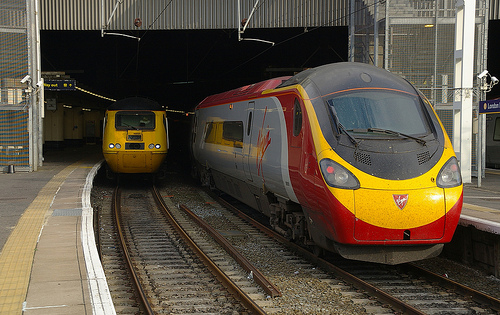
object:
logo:
[392, 194, 409, 211]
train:
[195, 62, 465, 264]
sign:
[46, 99, 57, 111]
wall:
[28, 99, 87, 141]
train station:
[2, 0, 498, 178]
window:
[335, 94, 431, 134]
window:
[203, 121, 245, 146]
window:
[292, 98, 302, 136]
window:
[247, 111, 252, 135]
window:
[117, 115, 152, 128]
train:
[101, 96, 170, 179]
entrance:
[32, 22, 363, 176]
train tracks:
[109, 187, 261, 314]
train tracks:
[202, 267, 490, 314]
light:
[155, 144, 161, 149]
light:
[109, 143, 115, 148]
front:
[103, 102, 167, 166]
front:
[305, 58, 465, 259]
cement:
[1, 149, 117, 314]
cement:
[430, 157, 499, 220]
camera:
[17, 74, 45, 96]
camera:
[475, 65, 497, 96]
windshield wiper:
[326, 100, 360, 146]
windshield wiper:
[339, 127, 426, 144]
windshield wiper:
[119, 120, 137, 130]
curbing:
[0, 154, 76, 312]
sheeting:
[1, 0, 498, 28]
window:
[8, 89, 23, 105]